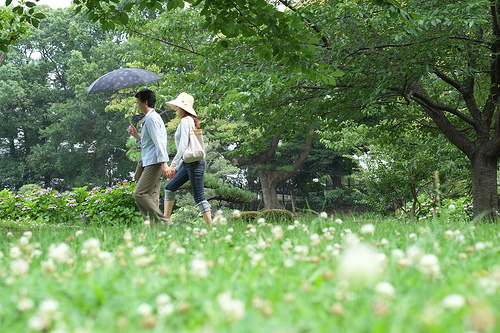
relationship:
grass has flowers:
[23, 232, 467, 323] [333, 226, 392, 298]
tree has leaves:
[329, 24, 499, 213] [380, 44, 423, 77]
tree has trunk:
[329, 24, 499, 213] [465, 147, 500, 241]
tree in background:
[329, 24, 499, 213] [5, 0, 500, 225]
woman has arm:
[167, 86, 219, 200] [164, 134, 212, 176]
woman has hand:
[167, 86, 219, 200] [165, 164, 174, 177]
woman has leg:
[167, 86, 219, 200] [182, 185, 217, 224]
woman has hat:
[167, 86, 219, 200] [172, 95, 197, 112]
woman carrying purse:
[167, 86, 219, 200] [179, 141, 211, 163]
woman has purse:
[167, 86, 219, 200] [179, 141, 211, 163]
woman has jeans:
[167, 86, 219, 200] [169, 152, 210, 207]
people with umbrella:
[130, 60, 221, 213] [90, 57, 186, 100]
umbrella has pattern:
[90, 57, 186, 100] [102, 72, 133, 88]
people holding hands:
[130, 60, 221, 213] [156, 159, 185, 185]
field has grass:
[17, 195, 467, 306] [23, 232, 467, 323]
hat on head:
[172, 95, 197, 112] [164, 87, 198, 128]